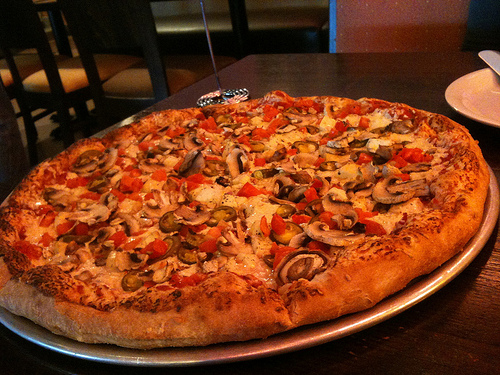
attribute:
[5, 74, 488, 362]
pizza — brown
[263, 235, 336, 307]
mushroom — brown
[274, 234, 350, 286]
mushroom — brown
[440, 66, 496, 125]
plate — white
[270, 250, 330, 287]
mushroom — brown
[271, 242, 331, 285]
mushroom — brown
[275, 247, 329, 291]
mushroom — brown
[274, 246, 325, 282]
mushroom — brown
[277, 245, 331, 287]
mushroom — brown